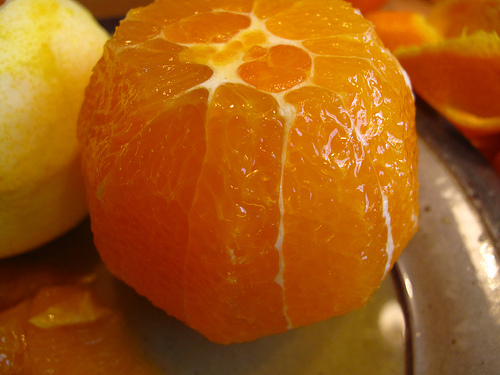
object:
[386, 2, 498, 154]
peels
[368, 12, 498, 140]
rind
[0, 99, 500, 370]
plate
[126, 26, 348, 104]
top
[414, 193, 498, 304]
tray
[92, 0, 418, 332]
white lines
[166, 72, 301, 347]
slice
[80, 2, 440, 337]
orange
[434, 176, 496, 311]
reflection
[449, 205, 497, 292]
light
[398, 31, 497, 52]
pith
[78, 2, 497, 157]
background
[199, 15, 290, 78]
healthy pith